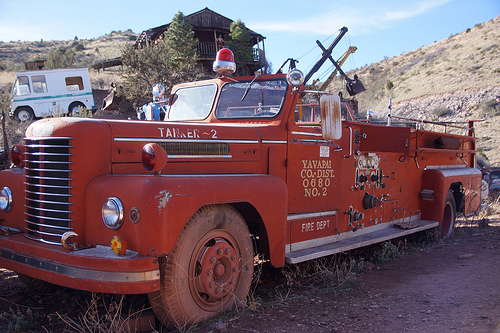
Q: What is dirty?
A: Tire.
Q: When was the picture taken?
A: Daytime.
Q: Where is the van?
A: To the left of the fire truck.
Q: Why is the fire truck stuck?
A: Mud.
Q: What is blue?
A: Sky.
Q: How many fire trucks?
A: One.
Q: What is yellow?
A: Words.